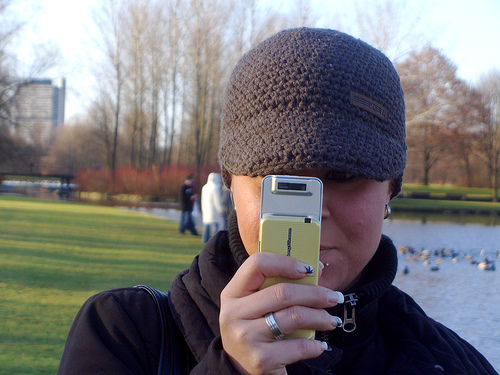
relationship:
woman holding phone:
[57, 27, 498, 374] [258, 172, 326, 343]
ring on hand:
[263, 311, 286, 339] [216, 250, 346, 374]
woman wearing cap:
[57, 27, 498, 374] [217, 26, 408, 197]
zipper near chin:
[338, 289, 360, 333] [312, 259, 351, 293]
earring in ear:
[383, 202, 395, 221] [383, 179, 393, 221]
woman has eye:
[57, 27, 498, 374] [323, 167, 355, 181]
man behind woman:
[177, 175, 200, 238] [57, 27, 498, 374]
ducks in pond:
[398, 243, 498, 277] [383, 209, 499, 374]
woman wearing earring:
[57, 27, 498, 374] [383, 202, 395, 221]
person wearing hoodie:
[201, 168, 224, 243] [201, 169, 226, 226]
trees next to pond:
[397, 48, 499, 194] [383, 209, 499, 374]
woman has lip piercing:
[57, 27, 498, 374] [323, 259, 333, 269]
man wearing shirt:
[177, 170, 200, 238] [180, 186, 197, 212]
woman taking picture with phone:
[57, 27, 498, 374] [258, 172, 326, 343]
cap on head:
[217, 26, 408, 197] [221, 26, 401, 297]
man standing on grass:
[177, 175, 200, 238] [3, 195, 208, 374]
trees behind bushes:
[82, 1, 227, 189] [79, 167, 201, 197]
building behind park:
[8, 75, 68, 145] [1, 152, 499, 374]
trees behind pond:
[397, 48, 499, 194] [383, 209, 499, 374]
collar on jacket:
[169, 229, 399, 353] [61, 229, 497, 374]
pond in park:
[383, 209, 499, 374] [1, 152, 499, 374]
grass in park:
[3, 195, 208, 374] [1, 152, 499, 374]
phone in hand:
[258, 172, 326, 343] [216, 250, 346, 374]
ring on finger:
[263, 311, 286, 339] [257, 304, 344, 338]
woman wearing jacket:
[57, 27, 498, 374] [61, 229, 497, 374]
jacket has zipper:
[61, 229, 497, 374] [338, 289, 360, 333]